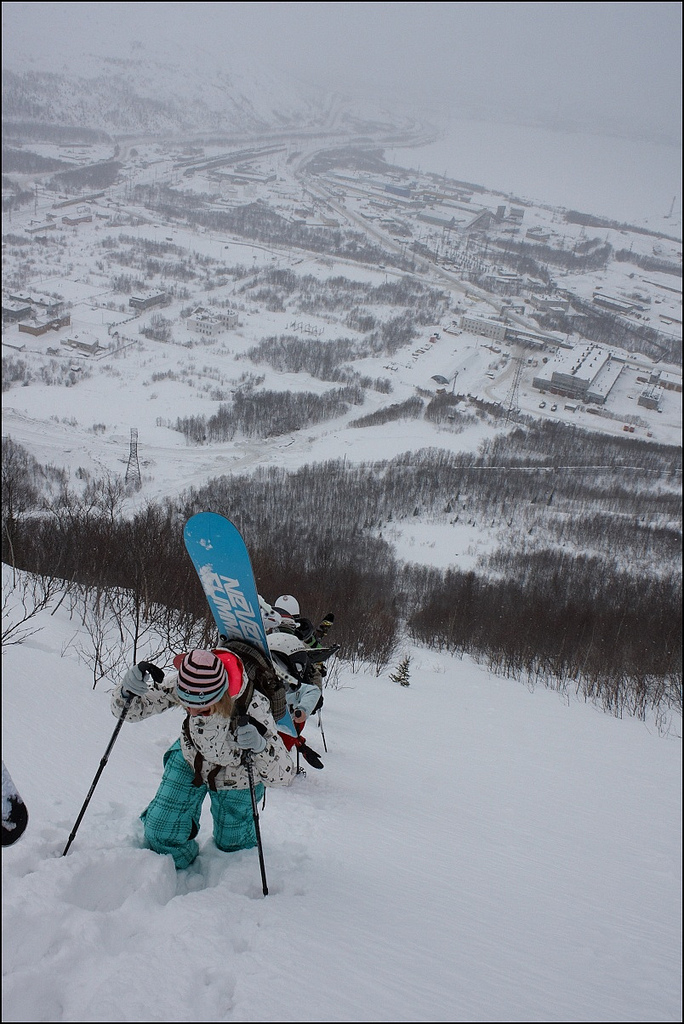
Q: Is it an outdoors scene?
A: Yes, it is outdoors.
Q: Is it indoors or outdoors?
A: It is outdoors.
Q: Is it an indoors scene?
A: No, it is outdoors.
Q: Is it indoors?
A: No, it is outdoors.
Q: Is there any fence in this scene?
A: No, there are no fences.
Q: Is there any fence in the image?
A: No, there are no fences.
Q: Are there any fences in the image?
A: No, there are no fences.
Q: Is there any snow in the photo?
A: Yes, there is snow.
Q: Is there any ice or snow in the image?
A: Yes, there is snow.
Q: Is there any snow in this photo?
A: Yes, there is snow.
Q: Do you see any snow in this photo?
A: Yes, there is snow.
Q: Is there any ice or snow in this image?
A: Yes, there is snow.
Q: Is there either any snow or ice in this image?
A: Yes, there is snow.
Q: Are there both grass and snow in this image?
A: No, there is snow but no grass.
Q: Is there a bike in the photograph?
A: No, there are no bikes.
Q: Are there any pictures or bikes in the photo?
A: No, there are no bikes or pictures.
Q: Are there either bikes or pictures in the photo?
A: No, there are no bikes or pictures.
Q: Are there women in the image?
A: Yes, there is a woman.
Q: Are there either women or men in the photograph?
A: Yes, there is a woman.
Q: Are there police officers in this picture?
A: No, there are no police officers.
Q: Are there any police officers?
A: No, there are no police officers.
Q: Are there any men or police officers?
A: No, there are no police officers or men.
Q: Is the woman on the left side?
A: Yes, the woman is on the left of the image.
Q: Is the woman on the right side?
A: No, the woman is on the left of the image.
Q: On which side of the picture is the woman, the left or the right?
A: The woman is on the left of the image.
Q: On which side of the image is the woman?
A: The woman is on the left of the image.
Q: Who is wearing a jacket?
A: The woman is wearing a jacket.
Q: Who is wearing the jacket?
A: The woman is wearing a jacket.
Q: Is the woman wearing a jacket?
A: Yes, the woman is wearing a jacket.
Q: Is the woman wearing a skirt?
A: No, the woman is wearing a jacket.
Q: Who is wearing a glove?
A: The woman is wearing a glove.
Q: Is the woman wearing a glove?
A: Yes, the woman is wearing a glove.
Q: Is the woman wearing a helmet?
A: No, the woman is wearing a glove.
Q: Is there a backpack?
A: Yes, there is a backpack.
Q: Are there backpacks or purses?
A: Yes, there is a backpack.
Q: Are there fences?
A: No, there are no fences.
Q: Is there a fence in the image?
A: No, there are no fences.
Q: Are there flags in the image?
A: No, there are no flags.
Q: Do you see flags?
A: No, there are no flags.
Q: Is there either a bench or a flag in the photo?
A: No, there are no flags or benches.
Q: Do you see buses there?
A: No, there are no buses.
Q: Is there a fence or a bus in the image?
A: No, there are no buses or fences.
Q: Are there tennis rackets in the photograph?
A: No, there are no tennis rackets.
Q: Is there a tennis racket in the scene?
A: No, there are no rackets.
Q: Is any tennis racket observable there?
A: No, there are no rackets.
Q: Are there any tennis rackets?
A: No, there are no tennis rackets.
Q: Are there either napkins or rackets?
A: No, there are no rackets or napkins.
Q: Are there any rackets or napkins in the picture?
A: No, there are no rackets or napkins.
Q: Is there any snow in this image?
A: Yes, there is snow.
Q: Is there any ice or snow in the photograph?
A: Yes, there is snow.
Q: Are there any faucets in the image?
A: No, there are no faucets.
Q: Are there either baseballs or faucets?
A: No, there are no faucets or baseballs.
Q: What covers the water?
A: The snow covers the water.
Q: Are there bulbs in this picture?
A: No, there are no bulbs.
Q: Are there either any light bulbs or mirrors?
A: No, there are no light bulbs or mirrors.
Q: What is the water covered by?
A: The water is covered by the snow.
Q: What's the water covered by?
A: The water is covered by the snow.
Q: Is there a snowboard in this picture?
A: Yes, there is a snowboard.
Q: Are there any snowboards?
A: Yes, there is a snowboard.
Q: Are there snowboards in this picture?
A: Yes, there is a snowboard.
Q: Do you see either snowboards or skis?
A: Yes, there is a snowboard.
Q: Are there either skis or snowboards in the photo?
A: Yes, there is a snowboard.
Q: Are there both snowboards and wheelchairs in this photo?
A: No, there is a snowboard but no wheelchairs.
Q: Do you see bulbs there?
A: No, there are no bulbs.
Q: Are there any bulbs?
A: No, there are no bulbs.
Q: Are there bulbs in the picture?
A: No, there are no bulbs.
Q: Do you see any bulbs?
A: No, there are no bulbs.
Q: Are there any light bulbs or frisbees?
A: No, there are no light bulbs or frisbees.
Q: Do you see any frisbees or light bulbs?
A: No, there are no light bulbs or frisbees.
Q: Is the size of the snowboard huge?
A: Yes, the snowboard is huge.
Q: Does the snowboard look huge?
A: Yes, the snowboard is huge.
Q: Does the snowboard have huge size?
A: Yes, the snowboard is huge.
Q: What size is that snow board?
A: The snow board is huge.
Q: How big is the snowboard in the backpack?
A: The snow board is huge.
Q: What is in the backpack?
A: The snowboard is in the backpack.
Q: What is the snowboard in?
A: The snowboard is in the backpack.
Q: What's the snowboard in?
A: The snowboard is in the backpack.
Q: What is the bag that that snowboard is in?
A: The bag is a backpack.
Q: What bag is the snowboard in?
A: The snowboard is in the backpack.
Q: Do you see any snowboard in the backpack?
A: Yes, there is a snowboard in the backpack.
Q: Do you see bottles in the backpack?
A: No, there is a snowboard in the backpack.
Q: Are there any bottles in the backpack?
A: No, there is a snowboard in the backpack.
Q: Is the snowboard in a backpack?
A: Yes, the snowboard is in a backpack.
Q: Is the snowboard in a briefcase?
A: No, the snowboard is in a backpack.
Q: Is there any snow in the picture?
A: Yes, there is snow.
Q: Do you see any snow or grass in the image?
A: Yes, there is snow.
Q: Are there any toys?
A: No, there are no toys.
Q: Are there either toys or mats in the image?
A: No, there are no toys or mats.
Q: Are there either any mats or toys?
A: No, there are no toys or mats.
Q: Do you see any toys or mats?
A: No, there are no toys or mats.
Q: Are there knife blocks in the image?
A: No, there are no knife blocks.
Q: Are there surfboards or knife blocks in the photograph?
A: No, there are no knife blocks or surfboards.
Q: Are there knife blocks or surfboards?
A: No, there are no knife blocks or surfboards.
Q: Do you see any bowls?
A: No, there are no bowls.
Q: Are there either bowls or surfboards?
A: No, there are no bowls or surfboards.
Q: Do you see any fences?
A: No, there are no fences.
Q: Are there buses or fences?
A: No, there are no fences or buses.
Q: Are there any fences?
A: No, there are no fences.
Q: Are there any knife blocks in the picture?
A: No, there are no knife blocks.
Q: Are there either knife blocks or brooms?
A: No, there are no knife blocks or brooms.